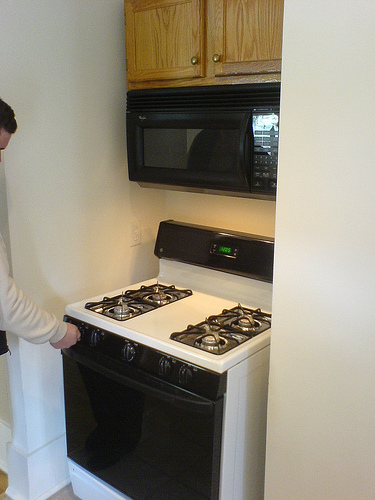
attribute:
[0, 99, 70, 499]
man — standing, white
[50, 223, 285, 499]
stove — electric, white, black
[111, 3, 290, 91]
cabinets — wooden, small, black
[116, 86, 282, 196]
microwave — black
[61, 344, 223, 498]
door — black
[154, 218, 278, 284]
part — top part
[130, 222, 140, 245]
outlet — wall outlet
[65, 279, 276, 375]
range top — gas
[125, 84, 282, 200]
microwave oven — mounted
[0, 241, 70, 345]
arm — sweatered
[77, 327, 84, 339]
knob — control knob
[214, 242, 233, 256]
display — time display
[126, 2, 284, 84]
cabinet — brown, blond oak, double doored cabinet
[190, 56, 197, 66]
knob — brass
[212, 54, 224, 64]
knob — brass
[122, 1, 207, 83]
door — cabinet door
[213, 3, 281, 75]
door — cabinet door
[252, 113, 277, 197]
control panel — microwave control panel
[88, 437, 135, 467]
reflection — feet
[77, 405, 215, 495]
reflection — floor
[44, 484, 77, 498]
floor — linoleum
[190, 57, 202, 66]
knob — gold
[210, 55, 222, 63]
knob — gold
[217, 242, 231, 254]
clock — blurry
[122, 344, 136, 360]
dial — stove dial, black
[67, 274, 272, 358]
stove top — burner stove top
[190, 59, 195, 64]
knob — gold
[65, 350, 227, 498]
window — oven window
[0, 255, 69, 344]
shirt — cream colored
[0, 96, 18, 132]
hair — brown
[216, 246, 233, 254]
clock — Electronic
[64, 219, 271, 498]
stove — White and black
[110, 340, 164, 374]
dials — black